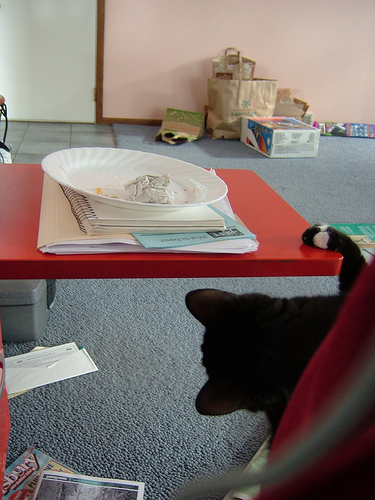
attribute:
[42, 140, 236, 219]
plate — empty, white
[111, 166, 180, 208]
napkin — used, crumbled, crumpled, rumpled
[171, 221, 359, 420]
cat — playing, black, leaning, holding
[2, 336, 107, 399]
envelope — lying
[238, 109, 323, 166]
box — cardboard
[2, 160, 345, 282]
table — orange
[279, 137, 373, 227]
carpet — gray, grey, blue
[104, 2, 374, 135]
wall — pink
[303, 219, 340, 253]
paw — black, white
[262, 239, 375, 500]
blanket — red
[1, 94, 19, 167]
stool — wood